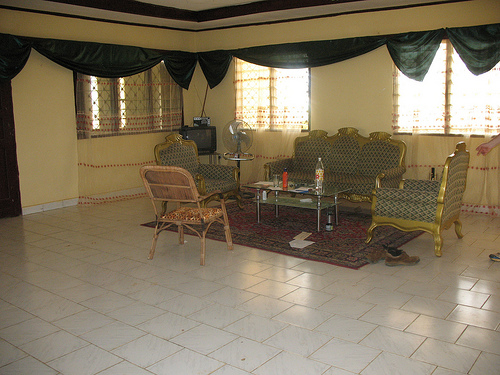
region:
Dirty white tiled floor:
[1, 192, 498, 374]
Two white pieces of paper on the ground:
[287, 229, 315, 250]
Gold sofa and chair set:
[152, 125, 470, 258]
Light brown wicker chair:
[137, 163, 232, 268]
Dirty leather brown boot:
[382, 244, 422, 267]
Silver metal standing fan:
[220, 116, 257, 201]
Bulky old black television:
[176, 120, 219, 155]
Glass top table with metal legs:
[244, 175, 354, 232]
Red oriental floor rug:
[140, 196, 429, 269]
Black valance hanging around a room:
[0, 19, 497, 216]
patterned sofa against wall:
[260, 124, 410, 213]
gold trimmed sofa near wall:
[258, 123, 410, 218]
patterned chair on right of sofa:
[355, 140, 475, 261]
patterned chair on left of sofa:
[148, 130, 248, 216]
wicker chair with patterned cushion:
[135, 162, 238, 272]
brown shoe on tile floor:
[378, 241, 421, 273]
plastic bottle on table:
[309, 155, 325, 194]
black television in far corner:
[175, 117, 220, 159]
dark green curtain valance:
[1, 18, 498, 88]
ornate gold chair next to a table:
[357, 141, 487, 258]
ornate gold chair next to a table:
[150, 130, 250, 217]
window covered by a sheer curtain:
[67, 54, 193, 144]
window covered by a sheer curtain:
[230, 52, 323, 133]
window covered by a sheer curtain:
[388, 26, 498, 137]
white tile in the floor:
[310, 308, 382, 345]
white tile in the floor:
[264, 298, 334, 336]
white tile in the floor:
[188, 298, 253, 333]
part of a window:
[446, 55, 498, 135]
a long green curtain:
[224, 34, 389, 74]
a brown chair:
[137, 158, 237, 264]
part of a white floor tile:
[0, 205, 140, 373]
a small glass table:
[242, 174, 356, 226]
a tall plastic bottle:
[312, 155, 324, 196]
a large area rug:
[137, 191, 423, 276]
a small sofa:
[262, 128, 406, 217]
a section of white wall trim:
[18, 195, 84, 213]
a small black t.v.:
[177, 122, 219, 156]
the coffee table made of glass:
[241, 177, 353, 232]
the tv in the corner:
[177, 125, 217, 153]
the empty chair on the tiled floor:
[140, 161, 233, 266]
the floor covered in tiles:
[0, 203, 497, 374]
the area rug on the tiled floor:
[140, 190, 427, 269]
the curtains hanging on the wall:
[2, 22, 497, 90]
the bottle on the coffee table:
[314, 156, 323, 188]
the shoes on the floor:
[362, 242, 419, 267]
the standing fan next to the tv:
[222, 118, 255, 198]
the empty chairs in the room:
[138, 125, 454, 265]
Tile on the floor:
[230, 312, 282, 341]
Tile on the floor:
[312, 333, 377, 373]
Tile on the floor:
[411, 335, 482, 371]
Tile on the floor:
[354, 302, 416, 332]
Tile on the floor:
[286, 281, 328, 310]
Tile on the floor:
[161, 288, 211, 318]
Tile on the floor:
[218, 265, 265, 290]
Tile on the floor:
[291, 267, 336, 285]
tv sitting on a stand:
[182, 123, 223, 153]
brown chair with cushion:
[136, 158, 237, 268]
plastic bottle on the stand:
[312, 151, 325, 198]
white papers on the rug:
[276, 225, 318, 257]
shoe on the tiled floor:
[380, 236, 425, 269]